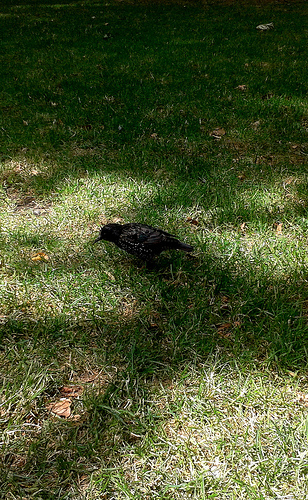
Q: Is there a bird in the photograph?
A: Yes, there is a bird.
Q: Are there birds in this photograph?
A: Yes, there is a bird.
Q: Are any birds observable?
A: Yes, there is a bird.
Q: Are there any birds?
A: Yes, there is a bird.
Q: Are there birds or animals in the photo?
A: Yes, there is a bird.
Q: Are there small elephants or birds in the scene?
A: Yes, there is a small bird.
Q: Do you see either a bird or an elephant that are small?
A: Yes, the bird is small.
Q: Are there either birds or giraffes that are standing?
A: Yes, the bird is standing.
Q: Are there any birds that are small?
A: Yes, there is a small bird.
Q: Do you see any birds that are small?
A: Yes, there is a bird that is small.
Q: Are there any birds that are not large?
A: Yes, there is a small bird.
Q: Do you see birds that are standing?
A: Yes, there is a bird that is standing.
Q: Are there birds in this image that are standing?
A: Yes, there is a bird that is standing.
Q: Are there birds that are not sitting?
A: Yes, there is a bird that is standing.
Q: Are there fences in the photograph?
A: No, there are no fences.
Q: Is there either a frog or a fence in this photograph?
A: No, there are no fences or frogs.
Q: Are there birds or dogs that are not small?
A: No, there is a bird but it is small.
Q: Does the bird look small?
A: Yes, the bird is small.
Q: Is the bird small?
A: Yes, the bird is small.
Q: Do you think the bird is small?
A: Yes, the bird is small.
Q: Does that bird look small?
A: Yes, the bird is small.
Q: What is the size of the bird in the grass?
A: The bird is small.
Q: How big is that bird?
A: The bird is small.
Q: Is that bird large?
A: No, the bird is small.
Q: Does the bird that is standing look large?
A: No, the bird is small.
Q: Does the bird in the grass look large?
A: No, the bird is small.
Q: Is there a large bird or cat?
A: No, there is a bird but it is small.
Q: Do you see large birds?
A: No, there is a bird but it is small.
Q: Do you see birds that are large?
A: No, there is a bird but it is small.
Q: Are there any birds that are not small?
A: No, there is a bird but it is small.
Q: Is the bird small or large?
A: The bird is small.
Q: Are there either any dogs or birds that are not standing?
A: No, there is a bird but it is standing.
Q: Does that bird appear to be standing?
A: Yes, the bird is standing.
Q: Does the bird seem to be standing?
A: Yes, the bird is standing.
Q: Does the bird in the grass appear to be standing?
A: Yes, the bird is standing.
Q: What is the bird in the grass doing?
A: The bird is standing.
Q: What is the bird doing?
A: The bird is standing.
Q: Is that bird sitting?
A: No, the bird is standing.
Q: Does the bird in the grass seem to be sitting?
A: No, the bird is standing.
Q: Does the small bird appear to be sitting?
A: No, the bird is standing.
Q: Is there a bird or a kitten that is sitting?
A: No, there is a bird but it is standing.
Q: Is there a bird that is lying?
A: No, there is a bird but it is standing.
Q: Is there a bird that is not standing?
A: No, there is a bird but it is standing.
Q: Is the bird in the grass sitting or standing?
A: The bird is standing.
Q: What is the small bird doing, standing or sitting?
A: The bird is standing.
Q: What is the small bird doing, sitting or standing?
A: The bird is standing.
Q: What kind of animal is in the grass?
A: The animal is a bird.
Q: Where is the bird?
A: The bird is in the grass.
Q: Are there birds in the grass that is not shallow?
A: Yes, there is a bird in the grass.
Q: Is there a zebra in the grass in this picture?
A: No, there is a bird in the grass.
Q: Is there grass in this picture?
A: Yes, there is grass.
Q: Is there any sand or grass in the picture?
A: Yes, there is grass.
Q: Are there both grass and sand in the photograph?
A: No, there is grass but no sand.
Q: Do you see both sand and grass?
A: No, there is grass but no sand.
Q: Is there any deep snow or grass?
A: Yes, there is deep grass.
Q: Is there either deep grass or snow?
A: Yes, there is deep grass.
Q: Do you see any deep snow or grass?
A: Yes, there is deep grass.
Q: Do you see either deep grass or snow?
A: Yes, there is deep grass.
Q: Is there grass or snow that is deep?
A: Yes, the grass is deep.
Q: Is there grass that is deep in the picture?
A: Yes, there is deep grass.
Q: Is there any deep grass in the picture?
A: Yes, there is deep grass.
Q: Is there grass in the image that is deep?
A: Yes, there is grass that is deep.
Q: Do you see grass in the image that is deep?
A: Yes, there is grass that is deep.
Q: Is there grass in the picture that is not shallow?
A: Yes, there is deep grass.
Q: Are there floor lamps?
A: No, there are no floor lamps.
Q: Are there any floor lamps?
A: No, there are no floor lamps.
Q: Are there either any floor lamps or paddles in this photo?
A: No, there are no floor lamps or paddles.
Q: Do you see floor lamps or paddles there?
A: No, there are no floor lamps or paddles.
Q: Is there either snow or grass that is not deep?
A: No, there is grass but it is deep.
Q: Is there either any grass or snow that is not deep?
A: No, there is grass but it is deep.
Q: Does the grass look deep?
A: Yes, the grass is deep.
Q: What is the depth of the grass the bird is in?
A: The grass is deep.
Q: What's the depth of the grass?
A: The grass is deep.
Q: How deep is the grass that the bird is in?
A: The grass is deep.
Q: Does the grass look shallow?
A: No, the grass is deep.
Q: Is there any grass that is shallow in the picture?
A: No, there is grass but it is deep.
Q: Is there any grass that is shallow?
A: No, there is grass but it is deep.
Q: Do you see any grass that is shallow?
A: No, there is grass but it is deep.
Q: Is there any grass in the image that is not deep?
A: No, there is grass but it is deep.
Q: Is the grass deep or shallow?
A: The grass is deep.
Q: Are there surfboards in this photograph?
A: No, there are no surfboards.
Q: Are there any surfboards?
A: No, there are no surfboards.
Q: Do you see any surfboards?
A: No, there are no surfboards.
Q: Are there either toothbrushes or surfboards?
A: No, there are no surfboards or toothbrushes.